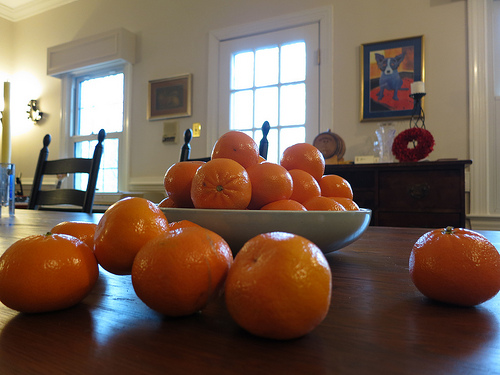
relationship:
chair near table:
[24, 126, 113, 216] [27, 206, 407, 374]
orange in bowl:
[189, 156, 252, 210] [156, 205, 371, 254]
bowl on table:
[156, 205, 371, 254] [368, 224, 498, 358]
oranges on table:
[198, 216, 363, 360] [7, 222, 488, 357]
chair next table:
[24, 126, 113, 216] [366, 241, 408, 293]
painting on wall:
[360, 32, 427, 124] [330, 7, 464, 153]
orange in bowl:
[196, 159, 248, 209] [164, 205, 370, 255]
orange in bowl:
[246, 160, 293, 203] [164, 205, 370, 255]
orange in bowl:
[290, 165, 319, 207] [164, 205, 370, 255]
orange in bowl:
[282, 168, 323, 207] [164, 205, 370, 255]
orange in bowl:
[306, 196, 345, 213] [164, 205, 370, 255]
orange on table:
[404, 221, 497, 311] [1, 198, 497, 373]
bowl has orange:
[156, 132, 373, 259] [185, 151, 256, 213]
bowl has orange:
[156, 132, 373, 259] [206, 127, 263, 171]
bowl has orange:
[156, 132, 373, 259] [280, 141, 325, 182]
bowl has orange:
[156, 132, 373, 259] [246, 158, 296, 200]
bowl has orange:
[156, 132, 373, 259] [161, 159, 211, 207]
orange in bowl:
[189, 156, 252, 210] [173, 200, 363, 253]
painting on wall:
[360, 32, 427, 124] [6, 1, 497, 235]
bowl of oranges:
[156, 205, 371, 254] [159, 118, 362, 212]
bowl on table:
[156, 205, 371, 254] [1, 198, 497, 373]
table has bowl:
[1, 198, 497, 373] [156, 205, 371, 254]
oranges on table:
[157, 128, 372, 258] [15, 209, 484, 364]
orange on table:
[0, 227, 96, 319] [15, 209, 484, 364]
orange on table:
[93, 196, 170, 278] [15, 209, 484, 364]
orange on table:
[129, 215, 231, 317] [15, 209, 484, 364]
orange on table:
[222, 225, 329, 339] [15, 209, 484, 364]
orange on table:
[405, 220, 496, 320] [15, 209, 484, 364]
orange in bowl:
[0, 227, 96, 319] [166, 201, 364, 241]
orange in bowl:
[93, 196, 170, 278] [166, 201, 364, 241]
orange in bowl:
[129, 215, 231, 317] [166, 201, 364, 241]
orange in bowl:
[222, 225, 329, 339] [166, 201, 364, 241]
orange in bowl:
[405, 220, 496, 320] [166, 201, 364, 241]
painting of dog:
[360, 32, 427, 124] [372, 56, 409, 100]